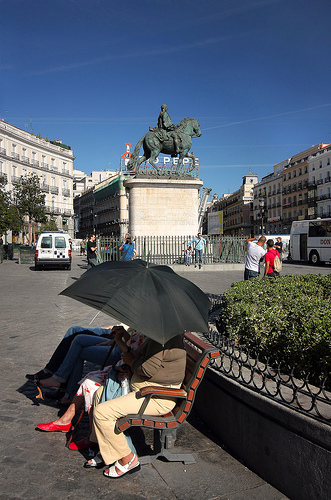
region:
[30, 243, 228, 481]
people sitting on bench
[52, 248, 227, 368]
people sitting under black umbrella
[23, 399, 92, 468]
lady wearing red shoes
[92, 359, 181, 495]
lady wearing brown pants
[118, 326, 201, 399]
lady wearing brown pants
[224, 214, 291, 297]
people standing taking pictures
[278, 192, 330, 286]
white bus parked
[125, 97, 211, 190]
statue of man on horse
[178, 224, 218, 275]
man and child standing against the fence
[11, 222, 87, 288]
white van parked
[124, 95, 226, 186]
Statue of a man on a horse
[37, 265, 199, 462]
Group of people sitting under umbrella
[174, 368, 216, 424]
The bench is made of wood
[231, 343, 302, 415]
Metal fencing around sidewalk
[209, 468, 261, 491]
Crack in the sidewalk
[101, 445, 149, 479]
Woman wearing strapped sandals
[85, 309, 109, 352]
Wire poking out on umbrella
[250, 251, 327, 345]
Bush in the middle of fence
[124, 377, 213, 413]
Arm on the bench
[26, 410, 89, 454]
Woman wearing red shoes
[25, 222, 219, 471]
people sitting on the bench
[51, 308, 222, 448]
the bench is reddish brown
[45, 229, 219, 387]
people under an umbrella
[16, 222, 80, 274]
a van is parked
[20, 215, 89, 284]
the van is white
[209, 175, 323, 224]
buildings in the background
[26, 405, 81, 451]
a person is wearing red shoes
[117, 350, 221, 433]
the bench is made of wood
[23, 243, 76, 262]
the brake lights are red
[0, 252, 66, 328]
the ground is grey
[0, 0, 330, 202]
a large area of blue sky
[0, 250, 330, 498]
a cobblestone courtyard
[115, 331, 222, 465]
a metal and wood bench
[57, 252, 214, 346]
a black umbrella held by a person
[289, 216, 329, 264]
a white bus in the background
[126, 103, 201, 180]
a statue of a man on a horse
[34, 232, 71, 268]
a white van in the background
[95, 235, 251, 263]
a green metal fence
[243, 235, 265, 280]
a man taking a photo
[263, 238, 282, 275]
a man with a red t-shirt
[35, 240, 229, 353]
an open black umbrella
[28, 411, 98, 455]
bright red shoes on feet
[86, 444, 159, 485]
a pair of white sandals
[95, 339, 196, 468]
brown shirt and tan pants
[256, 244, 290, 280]
red shirt with tan backpack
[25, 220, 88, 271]
back of a white van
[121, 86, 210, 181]
a man on a horse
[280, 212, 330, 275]
part of a white bus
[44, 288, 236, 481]
four people sitting on a bench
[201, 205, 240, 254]
a white and yellow billboard sign